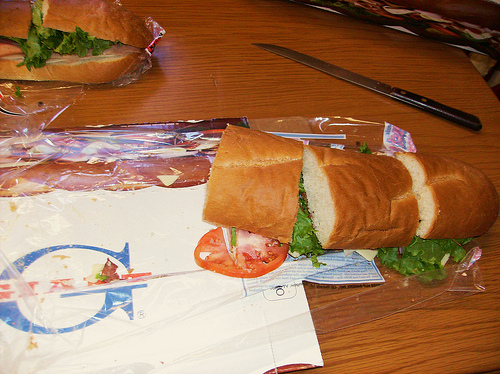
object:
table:
[1, 3, 499, 373]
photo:
[4, 4, 497, 373]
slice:
[226, 225, 270, 265]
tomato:
[193, 224, 293, 280]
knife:
[249, 39, 486, 135]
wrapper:
[163, 247, 486, 363]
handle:
[393, 82, 484, 134]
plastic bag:
[309, 114, 364, 131]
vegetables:
[15, 31, 92, 67]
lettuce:
[384, 241, 460, 281]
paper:
[0, 183, 326, 374]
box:
[39, 320, 82, 335]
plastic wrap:
[207, 116, 421, 161]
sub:
[202, 121, 499, 248]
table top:
[172, 22, 235, 99]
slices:
[204, 123, 419, 250]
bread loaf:
[0, 0, 151, 86]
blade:
[250, 33, 384, 103]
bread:
[310, 2, 499, 62]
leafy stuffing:
[291, 212, 317, 258]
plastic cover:
[0, 85, 50, 121]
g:
[0, 241, 138, 336]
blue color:
[81, 244, 99, 253]